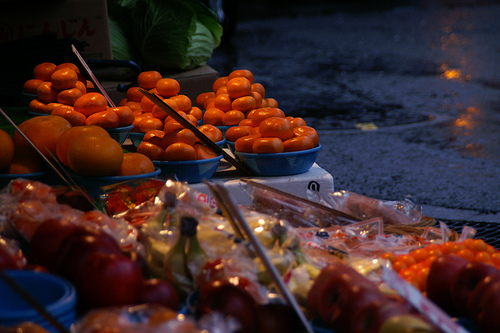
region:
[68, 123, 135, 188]
This is a tomato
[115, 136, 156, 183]
This is a tomato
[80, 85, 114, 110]
This is a tomato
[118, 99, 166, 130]
This is a tomato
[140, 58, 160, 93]
This is a tomato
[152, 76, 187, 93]
This is a tomato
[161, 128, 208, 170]
This is a tomato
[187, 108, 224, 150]
This is a tomato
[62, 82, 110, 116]
This is a tomato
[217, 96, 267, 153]
This is a tomato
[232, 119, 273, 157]
This is a tomato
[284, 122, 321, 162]
This is a tomato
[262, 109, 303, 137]
This is a tomato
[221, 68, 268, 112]
This is a tomato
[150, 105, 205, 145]
This is a tomato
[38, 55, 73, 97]
This is a tomato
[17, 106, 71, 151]
This is a tomato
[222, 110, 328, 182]
mandarin oranges in a blue bowl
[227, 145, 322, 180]
blue ceramic bowl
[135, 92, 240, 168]
wooden stick next to blue bowl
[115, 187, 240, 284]
bananas in plastic wrapping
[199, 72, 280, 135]
oranges in a pile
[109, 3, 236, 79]
dark green leaves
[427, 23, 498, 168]
reflection of light on the ground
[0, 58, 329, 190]
many bowls of oranges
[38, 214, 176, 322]
round red fruit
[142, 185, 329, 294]
bunches of yellow bananas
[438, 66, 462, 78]
Brightest light reflecting off the ground.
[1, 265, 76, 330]
A round blue container.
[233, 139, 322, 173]
A blue bowl full of oranges on the edge of a white table.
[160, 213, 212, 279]
The closest two bananas that are attached.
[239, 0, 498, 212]
A grey road with light reflecting on it.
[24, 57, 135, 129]
Two furthest back stacks of oranges.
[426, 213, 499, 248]
A metal grate in the road.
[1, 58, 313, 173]
All of the oranges in bowls.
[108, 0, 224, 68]
Heads of green cabbage.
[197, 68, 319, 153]
The front row of oranges.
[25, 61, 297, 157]
The oranges are in bowls.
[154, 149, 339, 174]
The bowls are blue.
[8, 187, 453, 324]
The tomatoes are in bags.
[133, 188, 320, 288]
The bananas are yellow.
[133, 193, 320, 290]
The bananas are in bags.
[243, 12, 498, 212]
The ground is concrete.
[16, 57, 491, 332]
The fruit is in the bowls.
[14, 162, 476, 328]
The fruit is in the bags.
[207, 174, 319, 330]
The stick is brown.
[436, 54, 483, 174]
The lights are on.